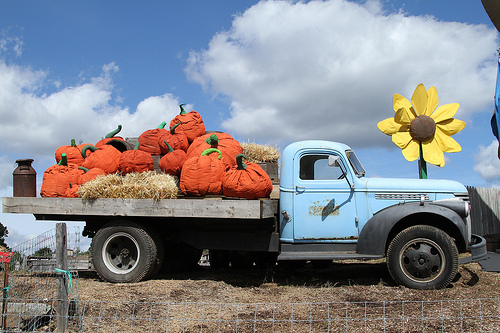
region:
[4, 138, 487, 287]
a parked pick up truck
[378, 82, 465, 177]
a fake yellow sunflower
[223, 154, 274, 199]
a fake orange pumpkin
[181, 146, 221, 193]
a fake orange pumpkin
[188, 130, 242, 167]
a fake orange pumpkin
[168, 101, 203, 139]
a fake orange pumpkin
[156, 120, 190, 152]
a fake orange pumpkin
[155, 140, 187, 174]
a fake orange pumpkin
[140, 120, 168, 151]
a fake orange pumpkin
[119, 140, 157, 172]
a fake orange pumpkin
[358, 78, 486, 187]
large fabric sunflower on right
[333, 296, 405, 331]
area on silver metal fencing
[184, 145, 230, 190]
large orange pumpkin with stem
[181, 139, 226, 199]
orange fabric pumkin on truck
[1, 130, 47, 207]
rusted metal milk jug on truck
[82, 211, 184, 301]
rear right wheel on truck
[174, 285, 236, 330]
patch of brown dirt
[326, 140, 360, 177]
silver side mirror on right side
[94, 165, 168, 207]
straw on back of truck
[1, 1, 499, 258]
A blue sky with clouds.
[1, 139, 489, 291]
A light blue truck.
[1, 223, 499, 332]
A wire fence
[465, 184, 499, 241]
A picket fence in the distance.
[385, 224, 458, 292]
A black wheel on a truck.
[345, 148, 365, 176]
A windshield of a truck.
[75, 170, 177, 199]
Hay on the back of a truck.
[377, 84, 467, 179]
A yellow paper flower.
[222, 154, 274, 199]
An orange paper pumpkin.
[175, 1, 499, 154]
A large white cloud in sky.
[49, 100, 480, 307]
this is a truck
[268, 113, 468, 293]
the truck is blue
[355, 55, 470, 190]
this is a sunflower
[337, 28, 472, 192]
the sunflower is fake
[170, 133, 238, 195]
this is a pumpkin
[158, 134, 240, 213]
the pumpkin is fake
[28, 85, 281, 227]
a group of fake pumpkins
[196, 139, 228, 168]
green stem on pumpkin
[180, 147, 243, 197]
the pumpkin is orange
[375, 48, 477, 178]
the sunflower is yellow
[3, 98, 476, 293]
Old blue farm truck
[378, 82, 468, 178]
Huge yellow sunflower sculpture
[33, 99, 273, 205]
Cloth pumpkins piled up on the back of a truck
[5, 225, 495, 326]
Top of a fence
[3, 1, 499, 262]
Blue sky with some clouds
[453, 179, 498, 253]
Unpainted old wooden fence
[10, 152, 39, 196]
Rusty old milk bucket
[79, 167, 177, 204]
Loose bunch of hay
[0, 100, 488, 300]
Old blue truck with wooden bed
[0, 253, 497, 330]
Dried out grassy field.